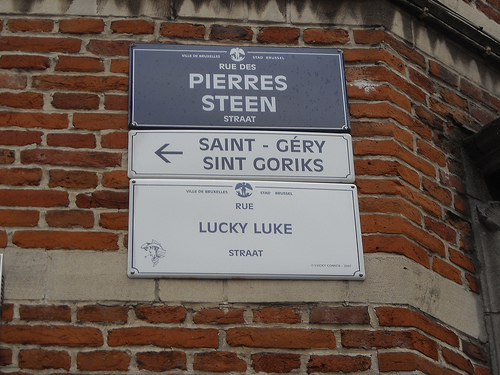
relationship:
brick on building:
[419, 172, 455, 208] [0, 0, 498, 373]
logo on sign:
[141, 239, 168, 266] [126, 178, 366, 280]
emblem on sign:
[233, 180, 252, 199] [125, 42, 366, 281]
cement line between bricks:
[2, 248, 489, 341] [0, 18, 499, 247]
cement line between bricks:
[2, 248, 489, 341] [1, 303, 499, 374]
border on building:
[126, 40, 352, 133] [0, 0, 498, 373]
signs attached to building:
[82, 35, 439, 275] [12, 24, 452, 372]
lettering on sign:
[185, 70, 291, 115] [127, 40, 352, 134]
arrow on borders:
[154, 142, 183, 163] [129, 131, 358, 184]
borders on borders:
[129, 131, 367, 282] [129, 131, 358, 184]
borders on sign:
[129, 131, 367, 282] [126, 178, 366, 280]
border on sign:
[126, 40, 352, 133] [131, 45, 344, 132]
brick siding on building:
[0, 15, 499, 374] [0, 0, 498, 373]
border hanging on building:
[126, 40, 352, 133] [42, 16, 400, 283]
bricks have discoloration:
[8, 54, 118, 177] [339, 73, 389, 93]